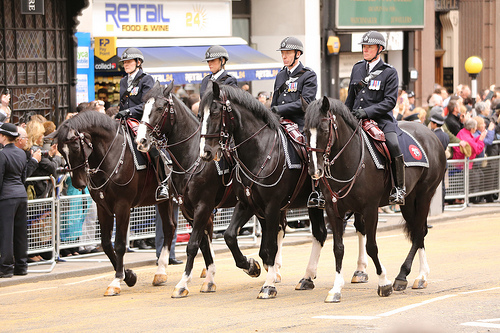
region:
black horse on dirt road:
[81, 105, 151, 277]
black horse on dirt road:
[152, 96, 213, 263]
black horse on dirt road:
[204, 67, 304, 251]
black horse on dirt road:
[327, 94, 417, 278]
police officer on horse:
[359, 45, 414, 140]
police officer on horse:
[254, 50, 321, 139]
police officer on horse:
[195, 50, 250, 144]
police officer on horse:
[123, 60, 178, 146]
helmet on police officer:
[361, 25, 383, 46]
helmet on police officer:
[272, 37, 316, 44]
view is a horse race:
[43, 77, 385, 293]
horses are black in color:
[103, 92, 410, 233]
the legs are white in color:
[308, 255, 369, 301]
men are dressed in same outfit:
[115, 66, 390, 113]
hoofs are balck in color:
[248, 282, 358, 300]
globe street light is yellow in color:
[465, 47, 489, 74]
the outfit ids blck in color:
[359, 68, 414, 131]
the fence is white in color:
[33, 197, 103, 253]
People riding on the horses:
[70, 23, 498, 235]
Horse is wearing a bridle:
[172, 77, 247, 174]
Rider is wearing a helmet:
[349, 13, 404, 48]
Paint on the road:
[350, 291, 410, 331]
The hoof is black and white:
[255, 276, 280, 307]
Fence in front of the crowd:
[47, 193, 104, 254]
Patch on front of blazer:
[368, 78, 390, 105]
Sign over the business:
[113, 12, 205, 42]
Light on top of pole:
[461, 43, 483, 79]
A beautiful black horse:
[300, 103, 461, 292]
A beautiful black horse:
[193, 88, 302, 286]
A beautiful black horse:
[129, 101, 207, 252]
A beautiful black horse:
[56, 89, 148, 295]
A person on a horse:
[260, 37, 310, 117]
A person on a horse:
[201, 48, 236, 103]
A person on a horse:
[108, 39, 168, 138]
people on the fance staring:
[456, 92, 498, 156]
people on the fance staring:
[18, 112, 78, 192]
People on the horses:
[38, 26, 460, 279]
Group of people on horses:
[65, 28, 442, 266]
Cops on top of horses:
[51, 39, 436, 239]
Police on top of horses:
[58, 39, 445, 242]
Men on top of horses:
[70, 40, 435, 257]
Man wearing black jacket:
[338, 18, 412, 172]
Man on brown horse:
[311, 25, 456, 298]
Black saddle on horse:
[342, 111, 442, 171]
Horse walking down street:
[298, 94, 469, 301]